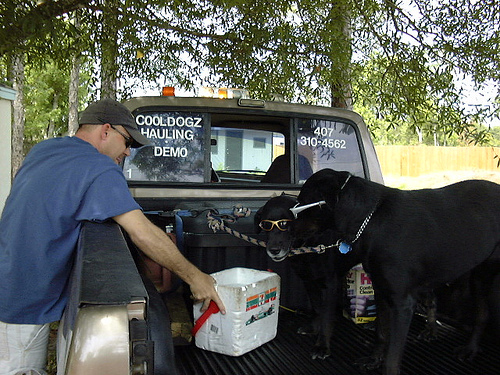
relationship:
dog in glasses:
[244, 190, 324, 351] [260, 218, 289, 230]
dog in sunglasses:
[290, 167, 498, 373] [288, 199, 328, 217]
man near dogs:
[0, 100, 225, 372] [250, 167, 498, 372]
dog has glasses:
[244, 190, 324, 351] [260, 211, 294, 225]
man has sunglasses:
[0, 106, 174, 371] [119, 131, 136, 149]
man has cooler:
[0, 100, 225, 372] [192, 267, 284, 357]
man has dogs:
[0, 100, 225, 372] [291, 169, 497, 371]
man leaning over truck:
[0, 100, 225, 372] [55, 94, 499, 374]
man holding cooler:
[0, 100, 225, 372] [192, 267, 284, 357]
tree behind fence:
[368, 14, 488, 139] [374, 130, 494, 172]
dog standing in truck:
[303, 167, 498, 362] [55, 54, 494, 369]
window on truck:
[208, 112, 300, 191] [55, 94, 499, 374]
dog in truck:
[244, 190, 324, 351] [42, 83, 399, 370]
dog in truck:
[303, 167, 498, 362] [42, 83, 399, 370]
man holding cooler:
[0, 106, 174, 371] [169, 240, 307, 370]